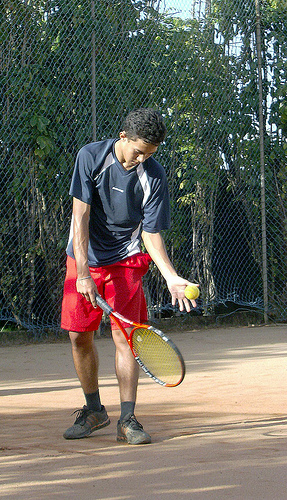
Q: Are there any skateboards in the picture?
A: No, there are no skateboards.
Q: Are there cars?
A: No, there are no cars.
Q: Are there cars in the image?
A: No, there are no cars.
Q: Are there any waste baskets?
A: No, there are no waste baskets.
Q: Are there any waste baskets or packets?
A: No, there are no waste baskets or packets.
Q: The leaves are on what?
A: The leaves are on the tree.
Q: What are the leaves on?
A: The leaves are on the tree.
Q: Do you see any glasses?
A: No, there are no glasses.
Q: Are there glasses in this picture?
A: No, there are no glasses.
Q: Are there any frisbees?
A: No, there are no frisbees.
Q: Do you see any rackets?
A: Yes, there is a racket.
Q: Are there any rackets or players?
A: Yes, there is a racket.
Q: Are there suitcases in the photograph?
A: No, there are no suitcases.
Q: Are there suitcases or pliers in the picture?
A: No, there are no suitcases or pliers.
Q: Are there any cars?
A: No, there are no cars.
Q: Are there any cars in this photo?
A: No, there are no cars.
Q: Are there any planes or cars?
A: No, there are no cars or planes.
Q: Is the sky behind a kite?
A: No, the sky is behind the fence.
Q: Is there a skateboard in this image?
A: No, there are no skateboards.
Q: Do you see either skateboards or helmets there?
A: No, there are no skateboards or helmets.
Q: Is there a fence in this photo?
A: Yes, there is a fence.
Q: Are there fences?
A: Yes, there is a fence.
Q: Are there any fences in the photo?
A: Yes, there is a fence.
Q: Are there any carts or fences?
A: Yes, there is a fence.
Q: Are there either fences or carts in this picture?
A: Yes, there is a fence.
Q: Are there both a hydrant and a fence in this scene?
A: No, there is a fence but no fire hydrants.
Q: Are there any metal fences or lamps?
A: Yes, there is a metal fence.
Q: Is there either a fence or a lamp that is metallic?
A: Yes, the fence is metallic.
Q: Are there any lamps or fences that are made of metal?
A: Yes, the fence is made of metal.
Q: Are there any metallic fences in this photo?
A: Yes, there is a metal fence.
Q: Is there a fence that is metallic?
A: Yes, there is a fence that is metallic.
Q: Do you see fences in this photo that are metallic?
A: Yes, there is a fence that is metallic.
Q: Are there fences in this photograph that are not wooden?
A: Yes, there is a metallic fence.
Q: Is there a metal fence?
A: Yes, there is a fence that is made of metal.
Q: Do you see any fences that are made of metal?
A: Yes, there is a fence that is made of metal.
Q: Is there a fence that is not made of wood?
A: Yes, there is a fence that is made of metal.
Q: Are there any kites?
A: No, there are no kites.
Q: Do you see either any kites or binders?
A: No, there are no kites or binders.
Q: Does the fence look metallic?
A: Yes, the fence is metallic.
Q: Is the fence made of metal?
A: Yes, the fence is made of metal.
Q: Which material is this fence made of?
A: The fence is made of metal.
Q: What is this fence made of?
A: The fence is made of metal.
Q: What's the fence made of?
A: The fence is made of metal.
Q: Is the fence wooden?
A: No, the fence is metallic.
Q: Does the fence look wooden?
A: No, the fence is metallic.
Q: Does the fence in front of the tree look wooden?
A: No, the fence is metallic.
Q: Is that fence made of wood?
A: No, the fence is made of metal.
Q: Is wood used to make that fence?
A: No, the fence is made of metal.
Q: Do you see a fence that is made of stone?
A: No, there is a fence but it is made of metal.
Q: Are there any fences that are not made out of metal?
A: No, there is a fence but it is made of metal.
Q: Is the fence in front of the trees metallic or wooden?
A: The fence is metallic.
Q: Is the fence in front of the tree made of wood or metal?
A: The fence is made of metal.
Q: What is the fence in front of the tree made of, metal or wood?
A: The fence is made of metal.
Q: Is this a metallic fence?
A: Yes, this is a metallic fence.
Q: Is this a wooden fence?
A: No, this is a metallic fence.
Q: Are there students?
A: No, there are no students.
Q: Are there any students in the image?
A: No, there are no students.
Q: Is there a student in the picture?
A: No, there are no students.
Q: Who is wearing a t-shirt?
A: The boy is wearing a t-shirt.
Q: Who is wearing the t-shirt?
A: The boy is wearing a t-shirt.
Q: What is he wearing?
A: The boy is wearing a tee shirt.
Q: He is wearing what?
A: The boy is wearing a tee shirt.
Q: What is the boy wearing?
A: The boy is wearing a tee shirt.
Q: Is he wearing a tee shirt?
A: Yes, the boy is wearing a tee shirt.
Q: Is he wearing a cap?
A: No, the boy is wearing a tee shirt.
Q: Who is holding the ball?
A: The boy is holding the ball.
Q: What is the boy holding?
A: The boy is holding the ball.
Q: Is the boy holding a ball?
A: Yes, the boy is holding a ball.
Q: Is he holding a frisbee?
A: No, the boy is holding a ball.